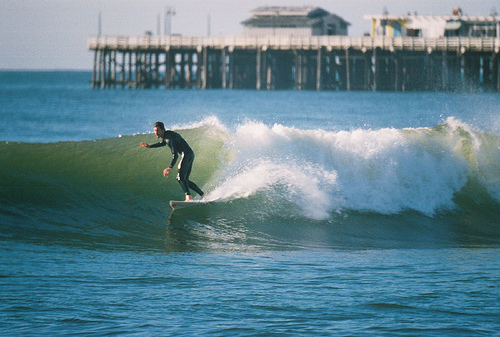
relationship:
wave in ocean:
[3, 118, 499, 218] [0, 95, 499, 336]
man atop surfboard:
[140, 120, 208, 200] [170, 199, 199, 210]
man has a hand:
[140, 120, 208, 200] [141, 140, 150, 150]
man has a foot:
[140, 120, 208, 200] [183, 195, 194, 202]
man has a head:
[140, 120, 208, 200] [155, 122, 165, 140]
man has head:
[140, 120, 208, 200] [155, 122, 165, 140]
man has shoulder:
[140, 120, 208, 200] [165, 127, 172, 145]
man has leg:
[140, 120, 208, 200] [178, 154, 190, 192]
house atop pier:
[241, 5, 353, 35] [91, 34, 499, 95]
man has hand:
[140, 120, 208, 200] [141, 140, 150, 150]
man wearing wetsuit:
[140, 120, 208, 200] [143, 119, 213, 213]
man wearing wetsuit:
[140, 120, 208, 200] [142, 130, 202, 208]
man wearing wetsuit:
[140, 120, 208, 200] [145, 135, 208, 191]